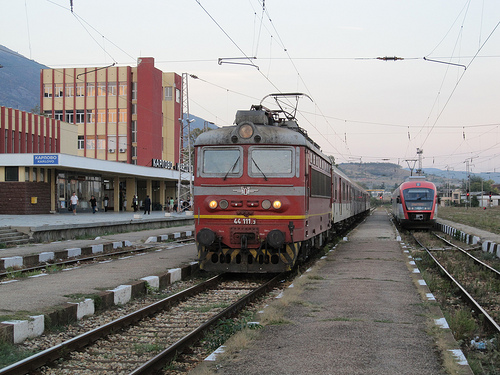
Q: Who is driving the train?
A: A conductor.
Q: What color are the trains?
A: Red.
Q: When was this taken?
A: During the day.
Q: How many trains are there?
A: Two.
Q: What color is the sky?
A: White.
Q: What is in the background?
A: Buildings.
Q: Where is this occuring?
A: A train station.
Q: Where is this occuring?
A: On tracks.